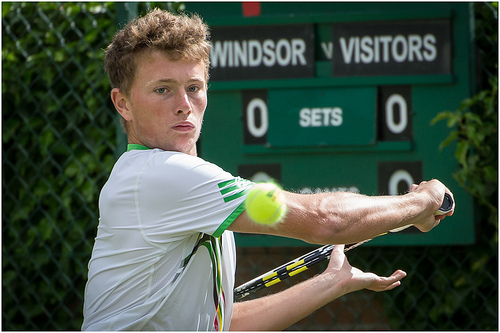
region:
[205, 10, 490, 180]
Tennis game score board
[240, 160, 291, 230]
a fuzzy green tennis ball in motion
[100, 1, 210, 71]
curly reddish hair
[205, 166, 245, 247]
green trim and design on a shirt sleeve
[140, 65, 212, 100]
a player's blue eyes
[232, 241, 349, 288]
yellow and black bands on the side of a tennis racquet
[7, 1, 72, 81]
a chain link fence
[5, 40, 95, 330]
Tall greenery beyond the tennis court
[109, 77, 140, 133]
a man's right ear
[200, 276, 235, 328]
multicolored stripes on a shirt front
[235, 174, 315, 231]
a tennis ball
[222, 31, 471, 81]
Windsor vs visitors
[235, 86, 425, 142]
sets 0 to 0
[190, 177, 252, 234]
a green sleeve of the player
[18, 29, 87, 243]
green leaves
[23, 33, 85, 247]
a picket fence that is chained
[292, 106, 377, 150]
the word sets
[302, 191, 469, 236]
the arm of the man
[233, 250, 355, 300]
a tennis racket ready to swing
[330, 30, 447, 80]
the word visitors on the scoreboard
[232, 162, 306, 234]
a yellow tennis ball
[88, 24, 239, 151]
a young man with bond hair and blue eyes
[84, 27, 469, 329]
a young man about to hit a tennis ball with his racket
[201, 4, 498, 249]
a green scored board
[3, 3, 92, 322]
a green iron fence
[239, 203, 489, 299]
a yellow and black tennis racket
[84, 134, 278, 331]
a white shirt with a green collar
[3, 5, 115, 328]
green foliage behind a green iron fence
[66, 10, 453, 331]
a young man looks at a yellow tennis ball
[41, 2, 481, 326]
a young man is ready to hit the ball with his tennis racket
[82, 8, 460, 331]
Young man with light brown/dark blond hair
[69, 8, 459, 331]
man watching a tennis ball approach him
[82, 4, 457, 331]
Young man getting ready to swing a tennis racket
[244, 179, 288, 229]
yellow tennis ball coming towards the young man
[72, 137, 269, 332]
white shirt with green edging around the neck and arm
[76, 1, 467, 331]
young man wearing a white t shirt with green edging around the neck and sleeves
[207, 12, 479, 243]
sign that tells the score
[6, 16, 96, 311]
chain link fence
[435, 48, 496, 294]
leaves from bush/tree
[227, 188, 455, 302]
black and yellow tennis racket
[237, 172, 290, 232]
Yellow tennis ball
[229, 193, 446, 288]
Black and yellow tennis racquet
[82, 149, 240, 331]
White and green athletic shirt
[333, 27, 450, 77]
Black and white 'visitors' sign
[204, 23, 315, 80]
Black and white 'windsor' sign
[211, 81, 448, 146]
Green sign displaying both sets are zero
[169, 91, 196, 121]
Nose of a human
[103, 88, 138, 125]
Ear of a human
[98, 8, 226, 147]
Face of a human being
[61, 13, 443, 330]
A male tennis player